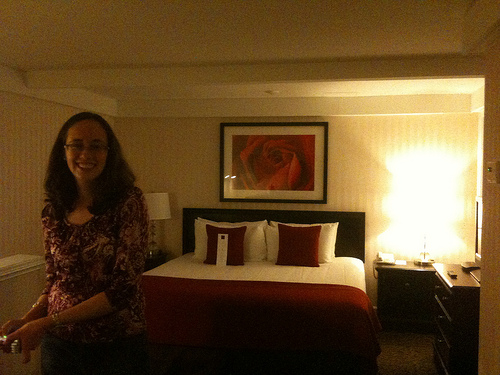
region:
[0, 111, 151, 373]
A brown haired woman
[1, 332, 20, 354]
A silver camera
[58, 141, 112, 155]
A pair of glasses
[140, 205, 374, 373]
A hotel bed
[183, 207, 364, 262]
A black head board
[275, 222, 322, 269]
A red throw pillow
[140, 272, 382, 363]
A red blanket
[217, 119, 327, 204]
A framed photo of a rose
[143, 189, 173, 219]
A white lamp shade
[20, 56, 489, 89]
A white beam along the ceiling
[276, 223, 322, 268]
a red pillow on a bed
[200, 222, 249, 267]
a red pillow on a bed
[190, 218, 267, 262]
a white pillow on a bed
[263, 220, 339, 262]
a white pillow on a bed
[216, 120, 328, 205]
a painting on a wall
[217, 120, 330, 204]
a painting of a rose on a wall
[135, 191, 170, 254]
a white lamp shade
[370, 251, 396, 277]
a phone on a counter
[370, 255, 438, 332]
a cabinet by a bed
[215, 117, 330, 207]
A photograph of a rose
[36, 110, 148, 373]
A pregnant woman standing in a bedroom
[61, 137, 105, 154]
Pair of glasses on a woman's face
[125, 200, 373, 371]
A queen sized bed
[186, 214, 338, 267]
Rust and cream decorative pillows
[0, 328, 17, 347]
A remote control in a woman's hand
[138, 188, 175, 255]
A lamp on a nightstand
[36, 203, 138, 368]
A long floral dress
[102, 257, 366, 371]
A rust comforter lying on a bed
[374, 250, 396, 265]
A white telephone sitting next to a bed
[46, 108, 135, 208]
face of the girl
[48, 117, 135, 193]
a girl with smiling face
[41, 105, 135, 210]
a girl with laughing face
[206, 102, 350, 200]
a painting on the back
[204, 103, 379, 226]
a poster in the back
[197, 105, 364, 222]
a poster in the wall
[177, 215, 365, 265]
two pillows on the bed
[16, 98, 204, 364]
girl in printed shirt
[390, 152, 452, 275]
bright light reflection on table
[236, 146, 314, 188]
red rose in the picture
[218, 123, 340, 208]
picture on the wall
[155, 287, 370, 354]
bed covering is red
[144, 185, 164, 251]
lamp on table is not on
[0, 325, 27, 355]
white item is being held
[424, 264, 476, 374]
dresser table on the side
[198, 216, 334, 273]
four pillows on the bed